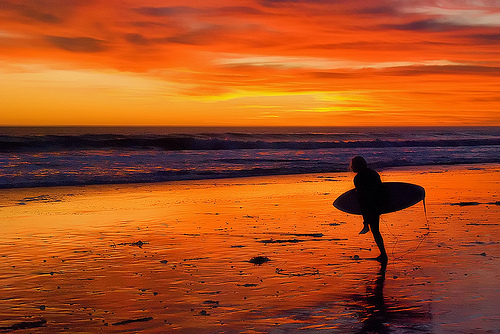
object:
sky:
[1, 0, 499, 133]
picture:
[1, 0, 499, 333]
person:
[330, 153, 422, 263]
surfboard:
[332, 181, 425, 217]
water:
[0, 123, 499, 187]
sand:
[0, 162, 500, 334]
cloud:
[213, 54, 463, 73]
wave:
[0, 131, 496, 151]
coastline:
[0, 150, 499, 201]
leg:
[368, 210, 390, 262]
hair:
[349, 153, 369, 175]